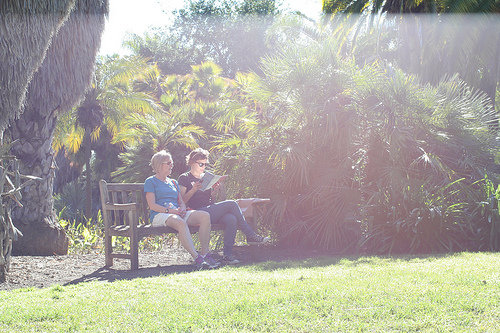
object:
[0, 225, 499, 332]
ground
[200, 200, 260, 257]
jeans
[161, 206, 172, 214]
wrist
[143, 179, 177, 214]
arm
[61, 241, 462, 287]
shadow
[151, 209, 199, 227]
shorts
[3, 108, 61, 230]
bark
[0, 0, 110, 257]
tree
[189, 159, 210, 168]
black sunglasses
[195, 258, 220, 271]
sneakers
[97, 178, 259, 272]
bench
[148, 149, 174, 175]
hair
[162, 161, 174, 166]
glasses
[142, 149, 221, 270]
woman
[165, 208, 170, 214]
watch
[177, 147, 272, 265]
woman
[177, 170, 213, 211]
shirt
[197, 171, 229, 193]
book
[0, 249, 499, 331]
grass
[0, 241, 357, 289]
gravel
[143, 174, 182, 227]
blue shirt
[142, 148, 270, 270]
two women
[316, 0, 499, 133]
trees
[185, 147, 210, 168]
hair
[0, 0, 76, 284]
tree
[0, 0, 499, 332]
sunshine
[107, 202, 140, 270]
arm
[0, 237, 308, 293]
path